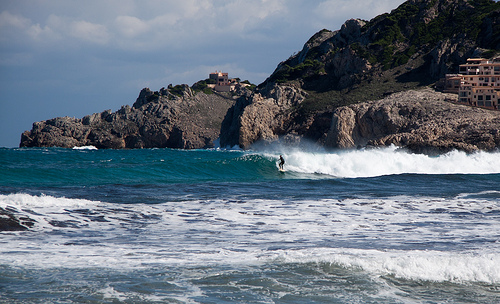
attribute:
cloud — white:
[1, 0, 299, 55]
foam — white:
[2, 189, 497, 302]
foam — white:
[214, 135, 499, 180]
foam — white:
[71, 140, 99, 150]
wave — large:
[237, 135, 499, 184]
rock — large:
[15, 1, 498, 167]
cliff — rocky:
[24, 14, 494, 161]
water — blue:
[33, 145, 495, 302]